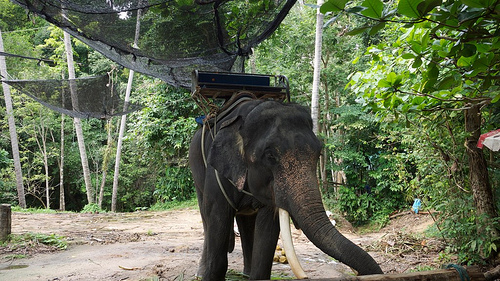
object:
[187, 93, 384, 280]
elephant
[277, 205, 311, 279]
tusk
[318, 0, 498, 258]
tree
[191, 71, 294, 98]
seat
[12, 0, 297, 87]
net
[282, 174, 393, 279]
trunk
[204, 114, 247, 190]
ear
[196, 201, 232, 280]
leg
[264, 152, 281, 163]
eye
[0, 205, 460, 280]
ground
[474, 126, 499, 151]
cloth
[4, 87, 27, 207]
stump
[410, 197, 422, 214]
ribbon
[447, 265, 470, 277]
plastic